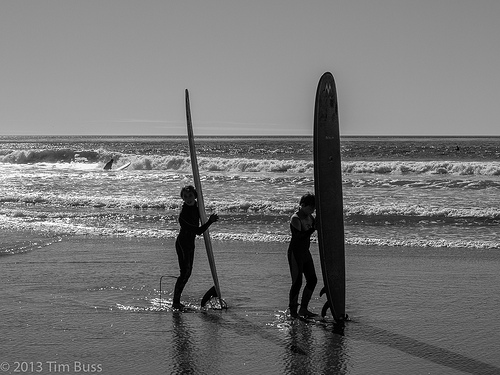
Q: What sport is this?
A: Surfing.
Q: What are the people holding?
A: Surfboards.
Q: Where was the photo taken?
A: Beach.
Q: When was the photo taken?
A: 2013.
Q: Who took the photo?
A: Tim Buss.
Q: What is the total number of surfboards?
A: 2.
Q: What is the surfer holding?
A: Surfboard.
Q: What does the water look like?
A: Wavy.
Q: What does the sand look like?
A: Wet.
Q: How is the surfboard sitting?
A: Standing on end.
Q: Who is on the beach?
A: Two surfers.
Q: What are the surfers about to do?
A: Surf.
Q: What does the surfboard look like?
A: Tall.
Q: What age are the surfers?
A: Children.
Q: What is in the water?
A: Surfer.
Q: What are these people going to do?
A: Surf.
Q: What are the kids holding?
A: Surfboards.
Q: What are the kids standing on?
A: Beach.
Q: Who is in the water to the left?
A: A surfboarder.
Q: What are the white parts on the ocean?
A: Waves.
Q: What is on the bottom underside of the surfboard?
A: Fins.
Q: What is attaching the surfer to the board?
A: Safety straps.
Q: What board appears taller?
A: The one on the right.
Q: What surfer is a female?
A: The one on the left.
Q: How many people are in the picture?
A: Two.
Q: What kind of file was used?
A: Black and white.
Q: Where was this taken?
A: On the beach.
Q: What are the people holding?
A: Surfboards.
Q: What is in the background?
A: The ocean and sky.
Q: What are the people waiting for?
A: Big waves.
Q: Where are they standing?
A: In shallow water.